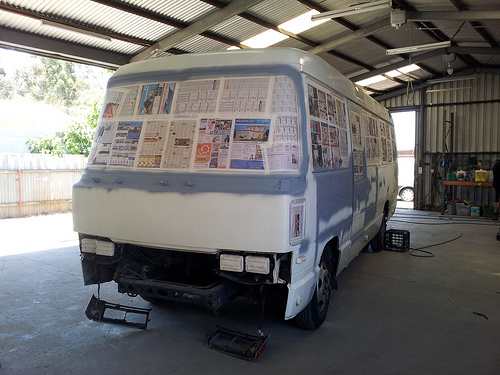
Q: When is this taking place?
A: Daytime.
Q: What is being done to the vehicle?
A: The vehicle is being painted.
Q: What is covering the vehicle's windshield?
A: Newspaper.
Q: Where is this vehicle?
A: Garage.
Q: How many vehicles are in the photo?
A: Two.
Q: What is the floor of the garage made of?
A: Concrete.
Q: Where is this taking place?
A: Garage.